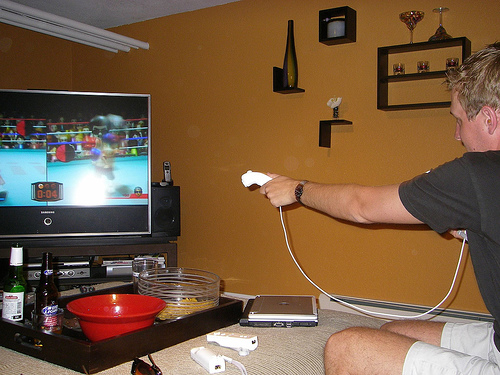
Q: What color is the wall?
A: Yellow.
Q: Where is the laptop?
A: On ottoman.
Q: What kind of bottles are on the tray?
A: Beer.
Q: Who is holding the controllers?
A: The man.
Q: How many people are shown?
A: One.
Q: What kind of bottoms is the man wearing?
A: Shorts.